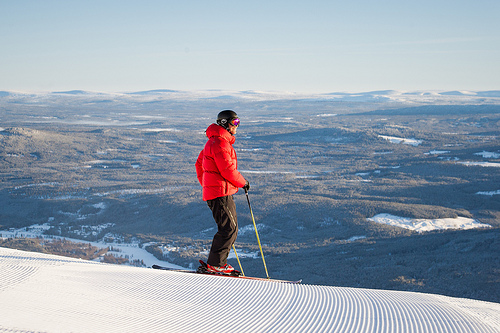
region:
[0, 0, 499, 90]
The sky above the person skiing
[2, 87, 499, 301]
The landscape beneath the person skiing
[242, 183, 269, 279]
A ski pole in the person's right hand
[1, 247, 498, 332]
A snowy hill beneath the pesrson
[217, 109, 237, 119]
The person is wearing a helmet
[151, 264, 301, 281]
Skis on the snow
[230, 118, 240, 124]
The person is wearing goggles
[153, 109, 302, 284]
A person standing on skis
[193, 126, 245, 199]
The person is wearing a jacket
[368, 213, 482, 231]
A large patch on snow on the landscape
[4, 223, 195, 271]
Frozen river in background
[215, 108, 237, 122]
Black helmet on skier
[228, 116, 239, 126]
Goggles on skier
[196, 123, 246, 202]
Red jacket on skier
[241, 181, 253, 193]
Gloves on skier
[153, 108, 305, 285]
Skier on top of mountain slope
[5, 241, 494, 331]
Groom tracks on ski slope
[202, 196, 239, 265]
Black pants on skier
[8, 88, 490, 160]
Mountains in distance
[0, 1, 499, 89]
Clear blue sky above skier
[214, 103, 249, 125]
black helmet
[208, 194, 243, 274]
black baggy pants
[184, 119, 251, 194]
red puffy jacket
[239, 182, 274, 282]
yellow ski rod in hand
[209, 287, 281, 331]
lines in snow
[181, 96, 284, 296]
person standing outside on skis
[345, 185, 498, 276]
snow covered land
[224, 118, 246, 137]
red and black goggles on face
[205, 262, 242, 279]
red and white snow boots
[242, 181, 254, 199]
black glove holding rod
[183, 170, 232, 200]
this is a man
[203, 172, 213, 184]
this is a skier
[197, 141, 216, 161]
this is a jacket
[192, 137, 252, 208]
the jacket is red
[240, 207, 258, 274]
this is a pole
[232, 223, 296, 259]
the pole is metal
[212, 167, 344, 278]
this is a ski pole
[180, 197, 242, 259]
this is a pair of pants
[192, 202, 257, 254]
the pants are black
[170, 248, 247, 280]
these are some shoes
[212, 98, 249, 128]
head of a person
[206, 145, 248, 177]
arm of a person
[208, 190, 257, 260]
leg of a person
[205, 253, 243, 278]
feet of a person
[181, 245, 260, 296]
a feet of a person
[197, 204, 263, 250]
a leg of a person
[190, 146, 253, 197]
an arm of a person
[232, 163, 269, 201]
hand of a person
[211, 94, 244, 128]
a head of a person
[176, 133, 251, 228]
body of a person